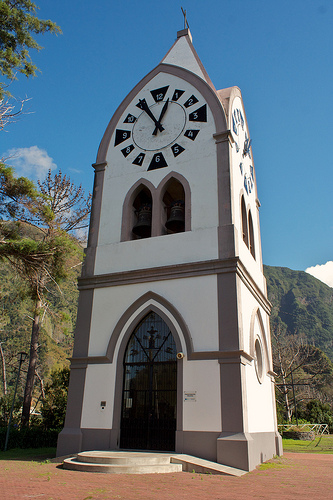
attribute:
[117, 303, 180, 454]
doorway — arched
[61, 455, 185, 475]
step — concrete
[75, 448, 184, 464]
step — concrete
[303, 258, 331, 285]
cloud — white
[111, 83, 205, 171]
clock — black, large, 12:55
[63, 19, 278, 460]
building — wheelchair accessible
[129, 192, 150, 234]
bell — brass, large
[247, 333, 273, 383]
window — round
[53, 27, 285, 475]
tower — alone, stands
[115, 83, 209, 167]
clock — large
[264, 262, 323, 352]
hill — green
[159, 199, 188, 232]
bell — identical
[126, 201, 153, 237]
bell — identical